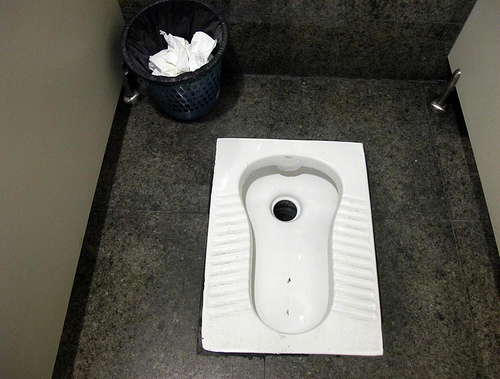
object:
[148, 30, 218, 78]
paper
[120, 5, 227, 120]
waste basket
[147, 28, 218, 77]
trash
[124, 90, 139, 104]
handle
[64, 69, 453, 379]
floor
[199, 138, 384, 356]
flush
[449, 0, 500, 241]
wall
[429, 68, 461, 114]
pipe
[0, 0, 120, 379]
wall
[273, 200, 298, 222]
circle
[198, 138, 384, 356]
square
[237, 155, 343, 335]
oval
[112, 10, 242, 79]
can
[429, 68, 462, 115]
object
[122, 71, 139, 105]
object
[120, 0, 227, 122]
bag